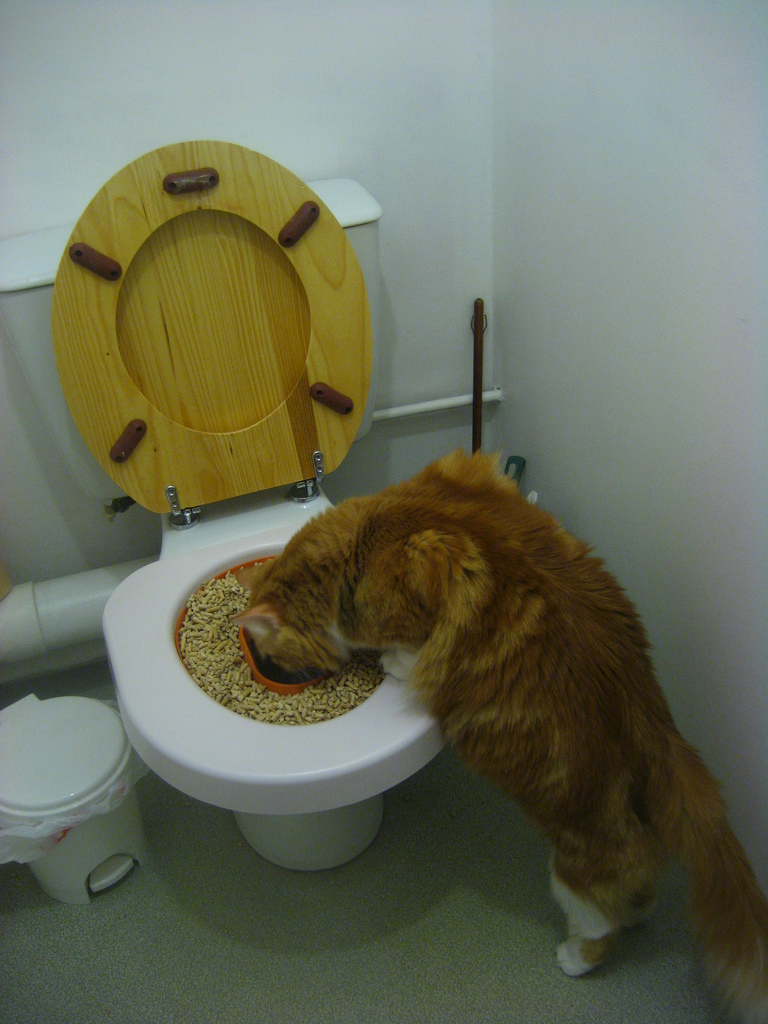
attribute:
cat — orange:
[225, 443, 765, 1022]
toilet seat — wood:
[46, 137, 372, 515]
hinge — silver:
[281, 444, 331, 504]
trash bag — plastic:
[2, 744, 129, 837]